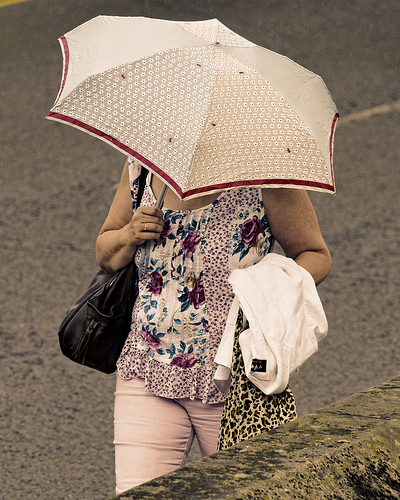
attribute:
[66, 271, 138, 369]
purse — black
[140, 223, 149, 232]
ring — small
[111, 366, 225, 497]
pants — pink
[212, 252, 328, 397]
jacket — white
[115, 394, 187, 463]
pants — pink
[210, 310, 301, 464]
coat — cheetah print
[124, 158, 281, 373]
blouse — tank top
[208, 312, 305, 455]
material — leopard print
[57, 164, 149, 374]
purse — black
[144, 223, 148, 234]
ring — gold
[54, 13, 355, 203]
umbrella — pink, lined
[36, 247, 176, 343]
bag — black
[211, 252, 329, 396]
coat — white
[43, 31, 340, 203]
line — red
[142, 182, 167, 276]
pole — metal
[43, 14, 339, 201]
design — floral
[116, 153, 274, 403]
design — floral